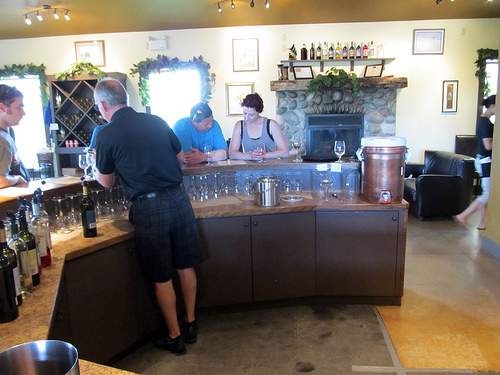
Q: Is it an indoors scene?
A: Yes, it is indoors.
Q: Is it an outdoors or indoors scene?
A: It is indoors.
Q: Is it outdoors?
A: No, it is indoors.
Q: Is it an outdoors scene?
A: No, it is indoors.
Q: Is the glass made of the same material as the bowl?
A: No, the glass is made of glass and the bowl is made of metal.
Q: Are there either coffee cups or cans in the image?
A: No, there are no coffee cups or cans.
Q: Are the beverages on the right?
A: Yes, the beverages are on the right of the image.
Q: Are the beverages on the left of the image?
A: No, the beverages are on the right of the image.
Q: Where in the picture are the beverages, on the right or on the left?
A: The beverages are on the right of the image.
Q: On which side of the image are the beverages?
A: The beverages are on the right of the image.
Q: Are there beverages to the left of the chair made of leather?
A: Yes, there are beverages to the left of the chair.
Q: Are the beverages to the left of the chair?
A: Yes, the beverages are to the left of the chair.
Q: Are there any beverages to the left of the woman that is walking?
A: Yes, there are beverages to the left of the woman.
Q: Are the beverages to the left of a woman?
A: Yes, the beverages are to the left of a woman.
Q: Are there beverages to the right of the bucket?
A: Yes, there are beverages to the right of the bucket.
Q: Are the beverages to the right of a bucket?
A: Yes, the beverages are to the right of a bucket.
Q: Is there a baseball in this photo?
A: No, there are no baseballs.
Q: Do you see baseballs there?
A: No, there are no baseballs.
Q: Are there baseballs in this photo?
A: No, there are no baseballs.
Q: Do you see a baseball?
A: No, there are no baseballs.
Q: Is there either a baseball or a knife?
A: No, there are no baseballs or knives.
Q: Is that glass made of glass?
A: Yes, the glass is made of glass.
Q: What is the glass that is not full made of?
A: The glass is made of glass.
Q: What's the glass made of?
A: The glass is made of glass.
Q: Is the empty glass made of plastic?
A: No, the glass is made of glass.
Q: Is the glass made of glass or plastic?
A: The glass is made of glass.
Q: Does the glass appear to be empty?
A: Yes, the glass is empty.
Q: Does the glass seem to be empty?
A: Yes, the glass is empty.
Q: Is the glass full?
A: No, the glass is empty.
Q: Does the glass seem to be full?
A: No, the glass is empty.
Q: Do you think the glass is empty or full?
A: The glass is empty.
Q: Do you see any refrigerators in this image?
A: No, there are no refrigerators.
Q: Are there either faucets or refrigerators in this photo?
A: No, there are no refrigerators or faucets.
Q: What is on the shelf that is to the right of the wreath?
A: The bottles are on the shelf.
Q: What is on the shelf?
A: The bottles are on the shelf.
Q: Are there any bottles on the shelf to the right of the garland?
A: Yes, there are bottles on the shelf.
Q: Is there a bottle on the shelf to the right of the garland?
A: Yes, there are bottles on the shelf.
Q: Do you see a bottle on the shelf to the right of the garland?
A: Yes, there are bottles on the shelf.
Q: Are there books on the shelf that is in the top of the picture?
A: No, there are bottles on the shelf.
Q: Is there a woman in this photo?
A: Yes, there is a woman.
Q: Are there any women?
A: Yes, there is a woman.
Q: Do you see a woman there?
A: Yes, there is a woman.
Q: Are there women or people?
A: Yes, there is a woman.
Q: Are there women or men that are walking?
A: Yes, the woman is walking.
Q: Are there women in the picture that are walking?
A: Yes, there is a woman that is walking.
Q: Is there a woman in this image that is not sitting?
A: Yes, there is a woman that is walking.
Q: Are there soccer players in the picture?
A: No, there are no soccer players.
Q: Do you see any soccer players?
A: No, there are no soccer players.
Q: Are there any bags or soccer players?
A: No, there are no soccer players or bags.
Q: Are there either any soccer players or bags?
A: No, there are no soccer players or bags.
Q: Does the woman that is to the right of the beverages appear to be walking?
A: Yes, the woman is walking.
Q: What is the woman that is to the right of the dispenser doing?
A: The woman is walking.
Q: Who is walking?
A: The woman is walking.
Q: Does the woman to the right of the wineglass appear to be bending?
A: No, the woman is walking.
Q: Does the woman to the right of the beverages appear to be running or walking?
A: The woman is walking.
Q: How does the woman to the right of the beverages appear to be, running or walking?
A: The woman is walking.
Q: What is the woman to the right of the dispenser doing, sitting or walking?
A: The woman is walking.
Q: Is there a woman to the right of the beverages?
A: Yes, there is a woman to the right of the beverages.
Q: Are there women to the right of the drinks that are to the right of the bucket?
A: Yes, there is a woman to the right of the beverages.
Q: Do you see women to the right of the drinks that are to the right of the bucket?
A: Yes, there is a woman to the right of the beverages.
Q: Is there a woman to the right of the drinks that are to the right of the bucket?
A: Yes, there is a woman to the right of the beverages.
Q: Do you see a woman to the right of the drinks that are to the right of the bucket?
A: Yes, there is a woman to the right of the beverages.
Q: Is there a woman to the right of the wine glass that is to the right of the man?
A: Yes, there is a woman to the right of the wineglass.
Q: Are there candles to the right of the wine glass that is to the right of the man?
A: No, there is a woman to the right of the wine glass.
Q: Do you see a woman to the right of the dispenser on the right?
A: Yes, there is a woman to the right of the dispenser.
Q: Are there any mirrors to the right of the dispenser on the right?
A: No, there is a woman to the right of the dispenser.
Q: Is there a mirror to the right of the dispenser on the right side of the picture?
A: No, there is a woman to the right of the dispenser.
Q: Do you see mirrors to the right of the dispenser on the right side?
A: No, there is a woman to the right of the dispenser.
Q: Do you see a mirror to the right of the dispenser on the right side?
A: No, there is a woman to the right of the dispenser.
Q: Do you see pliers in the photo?
A: No, there are no pliers.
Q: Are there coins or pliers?
A: No, there are no pliers or coins.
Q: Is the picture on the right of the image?
A: Yes, the picture is on the right of the image.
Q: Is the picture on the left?
A: No, the picture is on the right of the image.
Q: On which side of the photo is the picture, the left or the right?
A: The picture is on the right of the image.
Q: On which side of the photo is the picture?
A: The picture is on the right of the image.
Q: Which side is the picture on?
A: The picture is on the right of the image.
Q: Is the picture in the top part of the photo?
A: Yes, the picture is in the top of the image.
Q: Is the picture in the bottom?
A: No, the picture is in the top of the image.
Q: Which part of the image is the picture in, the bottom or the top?
A: The picture is in the top of the image.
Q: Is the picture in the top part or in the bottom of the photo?
A: The picture is in the top of the image.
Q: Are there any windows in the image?
A: Yes, there is a window.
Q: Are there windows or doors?
A: Yes, there is a window.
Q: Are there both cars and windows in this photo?
A: No, there is a window but no cars.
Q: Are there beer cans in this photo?
A: No, there are no beer cans.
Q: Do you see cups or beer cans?
A: No, there are no beer cans or cups.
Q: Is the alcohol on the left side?
A: Yes, the alcohol is on the left of the image.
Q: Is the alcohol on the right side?
A: No, the alcohol is on the left of the image.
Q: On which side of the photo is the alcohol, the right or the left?
A: The alcohol is on the left of the image.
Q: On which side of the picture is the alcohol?
A: The alcohol is on the left of the image.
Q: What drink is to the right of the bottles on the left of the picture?
A: The drink is alcohol.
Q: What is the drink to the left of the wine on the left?
A: The drink is alcohol.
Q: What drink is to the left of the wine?
A: The drink is alcohol.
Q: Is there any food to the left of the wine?
A: No, there is alcohol to the left of the wine.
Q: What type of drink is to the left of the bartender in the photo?
A: The drink is alcohol.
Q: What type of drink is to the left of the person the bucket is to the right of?
A: The drink is alcohol.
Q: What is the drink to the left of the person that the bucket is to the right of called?
A: The drink is alcohol.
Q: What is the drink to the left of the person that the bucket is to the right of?
A: The drink is alcohol.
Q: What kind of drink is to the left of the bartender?
A: The drink is alcohol.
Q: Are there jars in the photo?
A: No, there are no jars.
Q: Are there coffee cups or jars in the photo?
A: No, there are no jars or coffee cups.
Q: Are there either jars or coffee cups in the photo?
A: No, there are no jars or coffee cups.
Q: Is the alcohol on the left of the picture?
A: Yes, the alcohol is on the left of the image.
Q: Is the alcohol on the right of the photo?
A: No, the alcohol is on the left of the image.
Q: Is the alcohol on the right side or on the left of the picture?
A: The alcohol is on the left of the image.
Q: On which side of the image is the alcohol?
A: The alcohol is on the left of the image.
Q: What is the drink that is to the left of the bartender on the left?
A: The drink is alcohol.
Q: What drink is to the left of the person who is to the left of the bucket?
A: The drink is alcohol.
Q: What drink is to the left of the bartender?
A: The drink is alcohol.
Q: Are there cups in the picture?
A: No, there are no cups.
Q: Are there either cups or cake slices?
A: No, there are no cups or cake slices.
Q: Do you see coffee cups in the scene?
A: No, there are no coffee cups.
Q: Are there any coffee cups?
A: No, there are no coffee cups.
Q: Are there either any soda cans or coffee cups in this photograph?
A: No, there are no coffee cups or soda cans.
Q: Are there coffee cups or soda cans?
A: No, there are no coffee cups or soda cans.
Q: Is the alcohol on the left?
A: Yes, the alcohol is on the left of the image.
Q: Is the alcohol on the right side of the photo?
A: No, the alcohol is on the left of the image.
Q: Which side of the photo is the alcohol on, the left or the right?
A: The alcohol is on the left of the image.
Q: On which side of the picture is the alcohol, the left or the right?
A: The alcohol is on the left of the image.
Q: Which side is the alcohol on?
A: The alcohol is on the left of the image.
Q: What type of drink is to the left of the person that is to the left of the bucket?
A: The drink is alcohol.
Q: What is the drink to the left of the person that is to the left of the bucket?
A: The drink is alcohol.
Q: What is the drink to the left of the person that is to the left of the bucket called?
A: The drink is alcohol.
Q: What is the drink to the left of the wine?
A: The drink is alcohol.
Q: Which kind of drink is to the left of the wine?
A: The drink is alcohol.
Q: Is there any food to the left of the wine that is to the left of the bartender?
A: No, there is alcohol to the left of the wine.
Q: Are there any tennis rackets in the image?
A: No, there are no tennis rackets.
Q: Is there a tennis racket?
A: No, there are no rackets.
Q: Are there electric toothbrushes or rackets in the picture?
A: No, there are no rackets or electric toothbrushes.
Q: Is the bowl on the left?
A: Yes, the bowl is on the left of the image.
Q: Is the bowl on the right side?
A: No, the bowl is on the left of the image.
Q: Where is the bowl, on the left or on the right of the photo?
A: The bowl is on the left of the image.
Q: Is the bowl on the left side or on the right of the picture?
A: The bowl is on the left of the image.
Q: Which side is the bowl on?
A: The bowl is on the left of the image.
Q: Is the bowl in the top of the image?
A: No, the bowl is in the bottom of the image.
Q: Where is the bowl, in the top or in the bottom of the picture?
A: The bowl is in the bottom of the image.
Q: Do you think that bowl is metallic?
A: Yes, the bowl is metallic.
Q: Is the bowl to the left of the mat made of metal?
A: Yes, the bowl is made of metal.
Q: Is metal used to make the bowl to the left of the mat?
A: Yes, the bowl is made of metal.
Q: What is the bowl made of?
A: The bowl is made of metal.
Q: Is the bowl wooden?
A: No, the bowl is metallic.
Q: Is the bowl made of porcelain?
A: No, the bowl is made of metal.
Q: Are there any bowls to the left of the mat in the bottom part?
A: Yes, there is a bowl to the left of the mat.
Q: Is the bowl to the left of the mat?
A: Yes, the bowl is to the left of the mat.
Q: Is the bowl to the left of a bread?
A: No, the bowl is to the left of the mat.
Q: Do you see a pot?
A: No, there are no pots.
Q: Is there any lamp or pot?
A: No, there are no pots or lamps.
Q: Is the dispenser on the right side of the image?
A: Yes, the dispenser is on the right of the image.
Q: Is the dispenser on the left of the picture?
A: No, the dispenser is on the right of the image.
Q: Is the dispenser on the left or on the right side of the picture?
A: The dispenser is on the right of the image.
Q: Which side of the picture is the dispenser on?
A: The dispenser is on the right of the image.